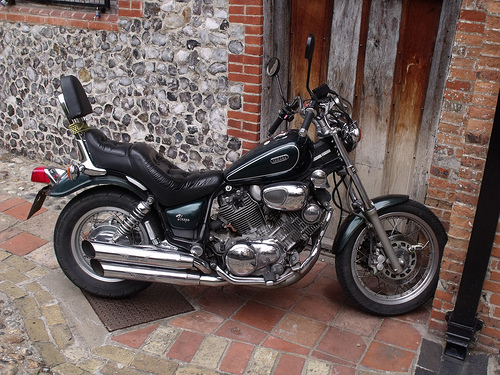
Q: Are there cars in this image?
A: No, there are no cars.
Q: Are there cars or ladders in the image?
A: No, there are no cars or ladders.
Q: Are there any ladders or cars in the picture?
A: No, there are no cars or ladders.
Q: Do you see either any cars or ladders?
A: No, there are no cars or ladders.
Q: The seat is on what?
A: The seat is on the bike.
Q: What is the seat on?
A: The seat is on the bike.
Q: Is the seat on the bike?
A: Yes, the seat is on the bike.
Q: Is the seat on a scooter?
A: No, the seat is on the bike.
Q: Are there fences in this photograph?
A: No, there are no fences.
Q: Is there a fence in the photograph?
A: No, there are no fences.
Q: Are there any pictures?
A: No, there are no pictures.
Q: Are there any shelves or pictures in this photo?
A: No, there are no pictures or shelves.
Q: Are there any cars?
A: No, there are no cars.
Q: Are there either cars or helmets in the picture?
A: No, there are no cars or helmets.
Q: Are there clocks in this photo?
A: No, there are no clocks.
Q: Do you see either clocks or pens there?
A: No, there are no clocks or pens.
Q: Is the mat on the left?
A: Yes, the mat is on the left of the image.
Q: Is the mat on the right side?
A: No, the mat is on the left of the image.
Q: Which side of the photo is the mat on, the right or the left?
A: The mat is on the left of the image.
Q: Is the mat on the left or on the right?
A: The mat is on the left of the image.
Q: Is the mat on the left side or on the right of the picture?
A: The mat is on the left of the image.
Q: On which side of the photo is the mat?
A: The mat is on the left of the image.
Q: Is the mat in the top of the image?
A: No, the mat is in the bottom of the image.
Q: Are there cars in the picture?
A: No, there are no cars.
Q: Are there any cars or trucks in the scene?
A: No, there are no cars or trucks.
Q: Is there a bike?
A: Yes, there is a bike.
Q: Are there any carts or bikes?
A: Yes, there is a bike.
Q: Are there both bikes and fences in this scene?
A: No, there is a bike but no fences.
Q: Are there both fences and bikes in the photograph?
A: No, there is a bike but no fences.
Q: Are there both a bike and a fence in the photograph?
A: No, there is a bike but no fences.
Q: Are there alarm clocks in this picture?
A: No, there are no alarm clocks.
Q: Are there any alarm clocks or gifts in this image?
A: No, there are no alarm clocks or gifts.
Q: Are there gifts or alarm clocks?
A: No, there are no alarm clocks or gifts.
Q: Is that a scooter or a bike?
A: That is a bike.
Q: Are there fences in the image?
A: No, there are no fences.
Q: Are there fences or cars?
A: No, there are no fences or cars.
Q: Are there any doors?
A: Yes, there is a door.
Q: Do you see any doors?
A: Yes, there is a door.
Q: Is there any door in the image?
A: Yes, there is a door.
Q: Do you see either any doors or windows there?
A: Yes, there is a door.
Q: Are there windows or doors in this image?
A: Yes, there is a door.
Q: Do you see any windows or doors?
A: Yes, there is a door.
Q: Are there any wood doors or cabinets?
A: Yes, there is a wood door.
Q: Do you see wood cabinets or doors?
A: Yes, there is a wood door.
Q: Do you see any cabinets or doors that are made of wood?
A: Yes, the door is made of wood.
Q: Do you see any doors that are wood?
A: Yes, there is a wood door.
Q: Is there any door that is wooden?
A: Yes, there is a door that is wooden.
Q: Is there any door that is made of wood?
A: Yes, there is a door that is made of wood.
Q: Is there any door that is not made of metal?
A: Yes, there is a door that is made of wood.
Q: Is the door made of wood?
A: Yes, the door is made of wood.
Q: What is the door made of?
A: The door is made of wood.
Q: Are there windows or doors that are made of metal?
A: No, there is a door but it is made of wood.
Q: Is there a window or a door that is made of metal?
A: No, there is a door but it is made of wood.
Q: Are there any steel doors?
A: No, there is a door but it is made of wood.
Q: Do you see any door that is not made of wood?
A: No, there is a door but it is made of wood.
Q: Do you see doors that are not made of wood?
A: No, there is a door but it is made of wood.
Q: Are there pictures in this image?
A: No, there are no pictures.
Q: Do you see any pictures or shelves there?
A: No, there are no pictures or shelves.